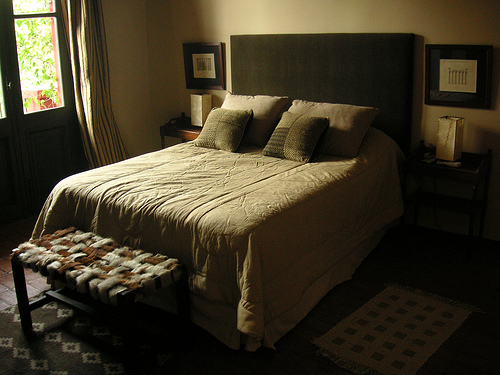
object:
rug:
[300, 277, 491, 375]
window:
[12, 0, 66, 117]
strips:
[68, 240, 160, 291]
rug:
[1, 293, 140, 373]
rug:
[0, 278, 214, 375]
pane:
[12, 14, 72, 115]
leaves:
[16, 25, 55, 87]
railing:
[50, 2, 72, 103]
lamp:
[190, 94, 213, 127]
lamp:
[434, 116, 465, 162]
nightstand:
[409, 147, 476, 245]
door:
[1, 0, 86, 218]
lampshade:
[434, 115, 466, 162]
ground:
[380, 150, 431, 185]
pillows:
[223, 92, 285, 150]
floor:
[351, 258, 448, 338]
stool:
[9, 226, 186, 360]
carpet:
[309, 279, 484, 374]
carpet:
[1, 286, 155, 373]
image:
[437, 56, 477, 92]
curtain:
[63, 0, 132, 170]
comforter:
[28, 129, 385, 314]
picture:
[182, 41, 227, 91]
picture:
[426, 46, 500, 110]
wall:
[145, 0, 498, 242]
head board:
[225, 31, 420, 158]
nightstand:
[411, 155, 497, 205]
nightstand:
[158, 116, 206, 145]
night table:
[157, 114, 201, 147]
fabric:
[228, 32, 412, 156]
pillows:
[264, 110, 329, 161]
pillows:
[193, 107, 253, 153]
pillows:
[285, 99, 378, 158]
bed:
[30, 32, 424, 351]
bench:
[10, 223, 190, 359]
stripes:
[59, 0, 130, 170]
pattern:
[43, 324, 97, 361]